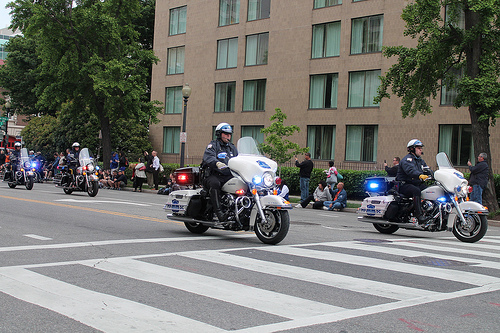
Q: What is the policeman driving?
A: A motorcycle.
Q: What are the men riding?
A: Motorcycles.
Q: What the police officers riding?
A: Motorcycles.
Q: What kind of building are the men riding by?
A: An apartment building.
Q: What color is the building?
A: Brown.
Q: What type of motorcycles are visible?
A: Police.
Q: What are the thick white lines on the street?
A: Crosswalk.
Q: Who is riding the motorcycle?
A: Police officers.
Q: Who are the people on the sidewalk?
A: Spectators.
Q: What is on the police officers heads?
A: Helmets.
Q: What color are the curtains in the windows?
A: White.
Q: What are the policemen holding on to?
A: Handlebars.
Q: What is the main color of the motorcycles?
A: White.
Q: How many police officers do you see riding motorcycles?
A: 4.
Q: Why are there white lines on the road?
A: A crosswalk.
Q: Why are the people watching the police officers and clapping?
A: In a parade.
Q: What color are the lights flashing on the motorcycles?
A: Red and Blue.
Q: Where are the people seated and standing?
A: On the curb.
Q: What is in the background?
A: Building.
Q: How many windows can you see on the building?
A: 23.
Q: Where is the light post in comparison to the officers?
A: It is in the background.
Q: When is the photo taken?
A: Daytime.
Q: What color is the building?
A: Brown.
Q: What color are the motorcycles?
A: White.